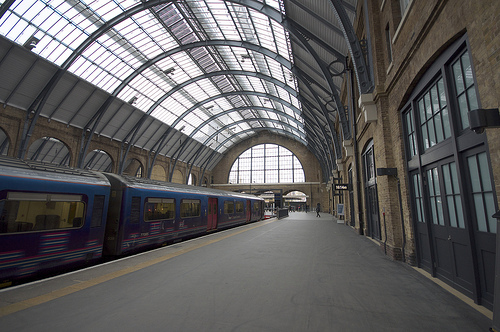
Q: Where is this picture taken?
A: In a train station.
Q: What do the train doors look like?
A: Red double doors.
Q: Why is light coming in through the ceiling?
A: There are windows on the ceiling.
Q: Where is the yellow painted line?
A: Next to the train.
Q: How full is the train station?
A: It is nearly empty.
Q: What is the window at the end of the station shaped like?
A: A half circle.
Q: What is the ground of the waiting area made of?
A: Cement.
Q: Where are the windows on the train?
A: On the side of the train.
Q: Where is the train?
A: In the train station.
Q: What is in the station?
A: A train.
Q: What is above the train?
A: Skylighting.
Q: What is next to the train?
A: Platform.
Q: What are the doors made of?
A: Wood.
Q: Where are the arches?
A: Above the train.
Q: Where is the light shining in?
A: The skylight.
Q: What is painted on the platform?
A: Yellow line.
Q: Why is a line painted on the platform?
A: For safety reasons.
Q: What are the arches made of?
A: Metal.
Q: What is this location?
A: Train station.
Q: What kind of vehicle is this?
A: Train.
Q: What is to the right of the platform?
A: Set of black doors.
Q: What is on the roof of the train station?
A: Glass windows.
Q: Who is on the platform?
A: One person.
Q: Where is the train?
A: In the station.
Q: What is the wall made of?
A: Brick.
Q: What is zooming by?
A: A train.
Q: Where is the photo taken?
A: A train station.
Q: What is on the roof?
A: Windows.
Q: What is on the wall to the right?
A: A door.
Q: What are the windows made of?
A: Glass.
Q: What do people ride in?
A: The train.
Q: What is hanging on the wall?
A: Lights.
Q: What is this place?
A: A train station.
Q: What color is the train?
A: Blue, red and silver.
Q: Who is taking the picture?
A: A photographer.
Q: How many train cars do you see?
A: 2.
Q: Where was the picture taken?
A: At a train station.